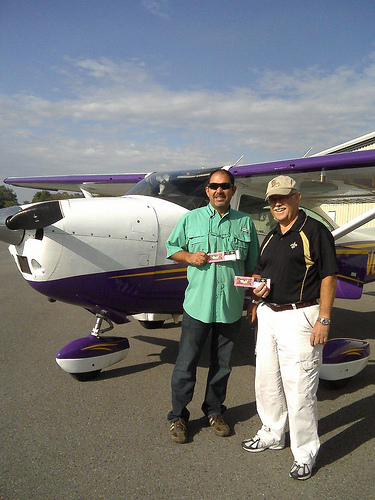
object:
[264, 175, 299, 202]
cap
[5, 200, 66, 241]
propeller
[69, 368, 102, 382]
wheel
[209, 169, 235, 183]
balding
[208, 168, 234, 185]
dark hair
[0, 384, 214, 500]
road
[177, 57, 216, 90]
wall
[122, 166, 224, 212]
window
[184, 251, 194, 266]
wrist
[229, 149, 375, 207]
wing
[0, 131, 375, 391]
plane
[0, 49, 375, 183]
clouds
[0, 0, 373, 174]
sky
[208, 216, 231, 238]
glasses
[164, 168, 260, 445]
man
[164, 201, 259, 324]
green shirt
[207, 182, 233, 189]
glasses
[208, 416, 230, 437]
shoe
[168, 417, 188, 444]
shoe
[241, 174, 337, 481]
man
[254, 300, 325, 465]
pants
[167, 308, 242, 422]
jeans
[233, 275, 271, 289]
ticket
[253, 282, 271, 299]
hand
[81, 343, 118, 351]
marks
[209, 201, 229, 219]
neck